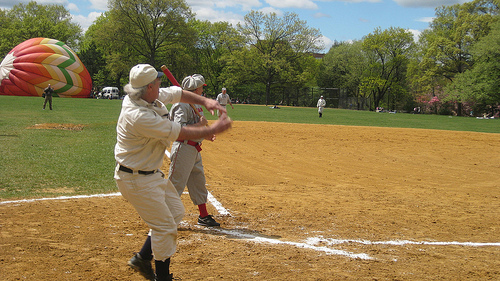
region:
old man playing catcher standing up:
[112, 65, 229, 279]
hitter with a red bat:
[160, 62, 218, 227]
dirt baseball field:
[1, 118, 497, 280]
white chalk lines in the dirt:
[0, 190, 499, 259]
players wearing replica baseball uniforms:
[115, 62, 230, 278]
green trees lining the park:
[2, 5, 498, 119]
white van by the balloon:
[100, 85, 117, 97]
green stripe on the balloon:
[55, 38, 75, 93]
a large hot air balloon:
[0, 37, 96, 96]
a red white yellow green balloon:
[0, 37, 92, 96]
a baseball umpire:
[115, 60, 233, 279]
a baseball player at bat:
[157, 61, 219, 231]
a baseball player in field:
[315, 93, 327, 115]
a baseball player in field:
[42, 83, 54, 108]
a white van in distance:
[97, 84, 119, 98]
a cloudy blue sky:
[2, 0, 446, 50]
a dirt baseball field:
[152, 119, 497, 278]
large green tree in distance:
[213, 8, 320, 108]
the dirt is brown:
[330, 140, 400, 185]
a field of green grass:
[41, 136, 93, 175]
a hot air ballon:
[3, 43, 64, 84]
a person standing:
[312, 90, 330, 118]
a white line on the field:
[305, 226, 366, 253]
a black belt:
[132, 166, 150, 178]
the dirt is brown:
[302, 138, 422, 193]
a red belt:
[182, 140, 198, 152]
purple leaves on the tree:
[425, 92, 440, 108]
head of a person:
[116, 66, 164, 104]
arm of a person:
[143, 106, 231, 154]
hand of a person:
[207, 103, 235, 150]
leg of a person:
[122, 178, 177, 272]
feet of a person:
[127, 236, 152, 274]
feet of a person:
[189, 206, 223, 231]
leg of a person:
[187, 168, 222, 205]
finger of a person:
[212, 89, 237, 114]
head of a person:
[183, 76, 217, 96]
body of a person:
[115, 85, 193, 180]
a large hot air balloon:
[5, 39, 88, 98]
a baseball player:
[165, 67, 229, 229]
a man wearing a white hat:
[113, 67, 190, 245]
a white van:
[97, 79, 117, 95]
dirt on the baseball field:
[233, 120, 455, 257]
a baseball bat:
[159, 63, 200, 107]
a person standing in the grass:
[314, 95, 325, 111]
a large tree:
[231, 17, 309, 97]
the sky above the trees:
[49, 0, 431, 26]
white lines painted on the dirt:
[234, 234, 349, 257]